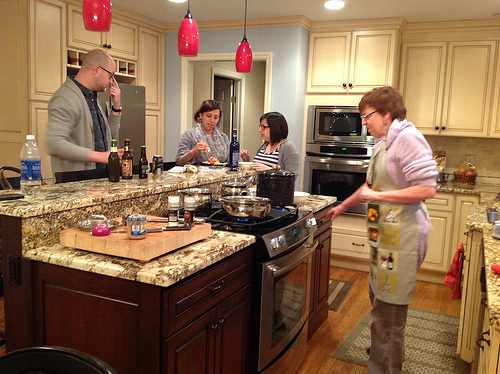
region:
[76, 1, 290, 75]
Red light containers strung on the cieling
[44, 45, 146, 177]
This man is touching the bridge of his glasses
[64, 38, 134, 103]
He is bald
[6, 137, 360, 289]
The counters are made of marble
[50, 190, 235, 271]
A thick cutting board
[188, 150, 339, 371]
The stove is silver and black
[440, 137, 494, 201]
Fruits in a basket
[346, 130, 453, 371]
She is wearing an apron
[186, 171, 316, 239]
Food is being cooked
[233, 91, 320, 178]
This woman is talking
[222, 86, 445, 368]
A WOMAN STANDING BY THE STOVE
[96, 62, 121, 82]
A PAIR OF GLASSES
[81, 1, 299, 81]
THREE OVERHEAD RED LIGHTS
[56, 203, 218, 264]
A WOODEN CUTTING BOARD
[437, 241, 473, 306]
A RED KITCHEN TOWEL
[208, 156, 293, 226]
THREE POTS ON THE STOVE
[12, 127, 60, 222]
A BOTTLE OF WATER ON THE COUNTER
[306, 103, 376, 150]
A MICROWAVE UNDER A CABINET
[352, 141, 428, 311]
A KITCHEN APRON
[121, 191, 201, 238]
SPICES ON A CUTTING BOARD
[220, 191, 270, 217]
Stainless steel cooking pot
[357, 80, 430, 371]
Woman wearing an apron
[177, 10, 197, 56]
Red glass light fixture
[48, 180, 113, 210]
Marble kitchen couter top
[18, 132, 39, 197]
Bottle of Aquafina water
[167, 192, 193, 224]
A pair of seasonings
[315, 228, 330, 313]
Cherry wood cabinet door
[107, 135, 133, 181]
Two unopened bottled beverages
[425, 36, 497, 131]
Beige colored cabinet doors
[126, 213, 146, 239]
Jar of cheese dip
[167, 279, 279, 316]
brown drawer under counter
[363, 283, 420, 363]
leg jeans of woman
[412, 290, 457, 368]
green rug in kitchen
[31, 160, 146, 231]
beige marble countertop in kitchen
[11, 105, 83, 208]
water bottle on counter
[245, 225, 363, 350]
stainless steel gray oven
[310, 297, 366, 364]
brown wood flooring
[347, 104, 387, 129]
glasses on the woman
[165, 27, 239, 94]
red overhead lights in kitchen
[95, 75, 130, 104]
left hand of guy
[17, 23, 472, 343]
A kitchen scene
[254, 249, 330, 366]
This is an oven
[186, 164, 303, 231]
Pots are on the stove top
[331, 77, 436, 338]
The woman is wearing an apron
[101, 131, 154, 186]
Three beer bottles are sitting on the counter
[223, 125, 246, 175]
A bottle of wine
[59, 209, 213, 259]
This is a wooden cutting board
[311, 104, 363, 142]
This is a microwave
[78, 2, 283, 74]
Lights are hanging from the ceiling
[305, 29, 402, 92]
Kitchen cabinets